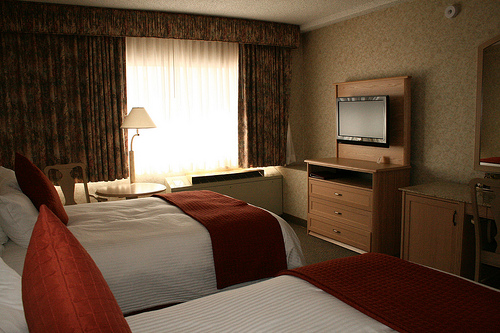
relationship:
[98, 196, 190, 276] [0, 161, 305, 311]
comforter on bed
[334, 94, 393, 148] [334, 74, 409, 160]
black tv hanging on wall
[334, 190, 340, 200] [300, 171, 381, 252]
knob on drawers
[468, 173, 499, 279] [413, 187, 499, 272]
chair at desk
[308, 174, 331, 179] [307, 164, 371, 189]
notebook on shelf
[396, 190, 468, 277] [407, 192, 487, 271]
door on cabinet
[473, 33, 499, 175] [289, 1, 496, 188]
mirror hanging on wall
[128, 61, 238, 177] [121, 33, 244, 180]
sunlight out of window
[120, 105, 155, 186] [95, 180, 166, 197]
lamp over table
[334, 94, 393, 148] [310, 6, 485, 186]
black tv on wall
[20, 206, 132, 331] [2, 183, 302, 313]
pillow on bed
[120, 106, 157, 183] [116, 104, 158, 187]
lamp with lamp shade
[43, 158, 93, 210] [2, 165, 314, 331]
wooden chair by bed